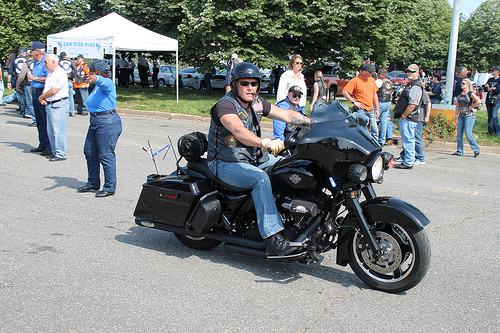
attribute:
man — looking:
[227, 68, 348, 250]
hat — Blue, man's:
[22, 37, 44, 52]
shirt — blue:
[86, 75, 118, 112]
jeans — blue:
[208, 150, 286, 240]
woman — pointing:
[75, 57, 139, 197]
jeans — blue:
[205, 160, 298, 255]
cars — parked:
[124, 56, 430, 96]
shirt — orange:
[342, 76, 377, 102]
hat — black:
[15, 33, 53, 58]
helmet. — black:
[226, 63, 265, 83]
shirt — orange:
[340, 67, 382, 112]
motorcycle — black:
[131, 98, 433, 293]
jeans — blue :
[204, 152, 314, 238]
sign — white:
[21, 19, 125, 76]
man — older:
[38, 51, 72, 164]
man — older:
[23, 41, 58, 156]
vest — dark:
[206, 95, 265, 160]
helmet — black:
[231, 62, 264, 83]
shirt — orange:
[350, 73, 378, 113]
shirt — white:
[278, 72, 309, 105]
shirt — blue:
[80, 75, 119, 126]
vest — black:
[209, 96, 273, 163]